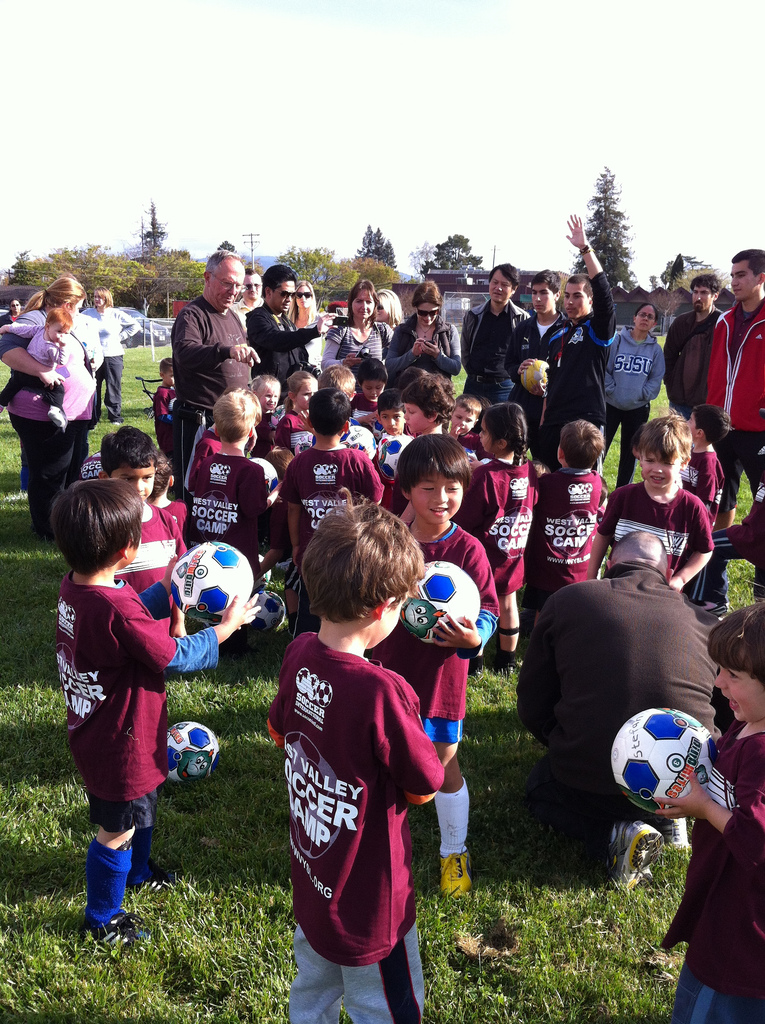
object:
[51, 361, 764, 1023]
kids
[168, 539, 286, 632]
balls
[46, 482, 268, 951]
child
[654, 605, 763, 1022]
child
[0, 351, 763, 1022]
field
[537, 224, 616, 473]
man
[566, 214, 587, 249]
hand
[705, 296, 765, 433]
coat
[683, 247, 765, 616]
man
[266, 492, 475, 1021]
child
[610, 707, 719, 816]
ball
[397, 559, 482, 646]
ball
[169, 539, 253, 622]
ball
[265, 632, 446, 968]
jersey